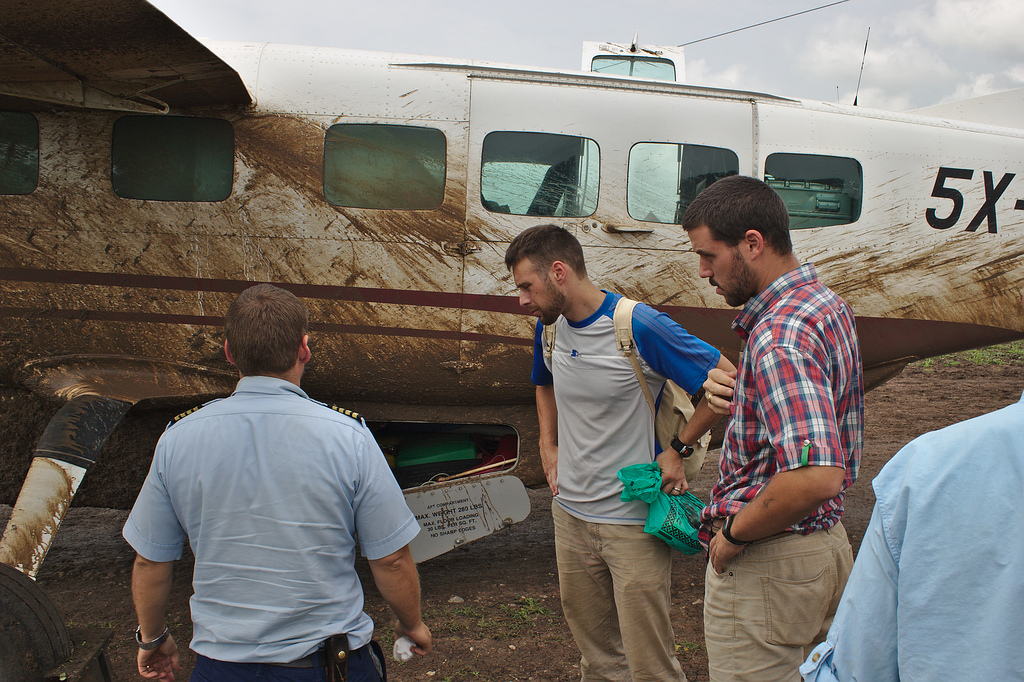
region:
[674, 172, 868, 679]
Young man wearing check shirt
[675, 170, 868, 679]
Man in check shirt wearing brown pants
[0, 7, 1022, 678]
Men standing close to the aircraft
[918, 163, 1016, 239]
5X on the aircraft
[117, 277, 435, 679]
Man in blue uniform has brown hair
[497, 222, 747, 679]
Man in gray and blue shirt has clean cut hair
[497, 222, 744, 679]
Man in gray and blue shirt wearing brown pants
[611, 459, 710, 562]
Blue plastic bag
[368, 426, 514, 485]
Luggages inside the compartment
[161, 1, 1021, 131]
cloud in daytime sky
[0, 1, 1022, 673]
plane above dirt surface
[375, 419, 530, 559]
open door of compartment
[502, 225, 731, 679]
man with straps on shoulders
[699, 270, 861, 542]
plaid shirt with short sleeves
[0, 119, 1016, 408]
mud on side of plane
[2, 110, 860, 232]
row of square windows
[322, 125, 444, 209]
surface of sirty window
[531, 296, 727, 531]
white shirt with blue sleeves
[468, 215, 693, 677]
man wearing white shirt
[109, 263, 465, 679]
man wearing blue shirt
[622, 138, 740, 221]
glass is clean and clear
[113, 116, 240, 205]
glass is clean and clear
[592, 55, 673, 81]
glass is clean and clear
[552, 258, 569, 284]
person has a white ear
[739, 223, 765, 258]
person has a white ear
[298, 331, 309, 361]
person has a white ear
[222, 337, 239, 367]
person has a white ear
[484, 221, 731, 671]
Man wearing blue and white shirt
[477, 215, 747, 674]
Man with dark hair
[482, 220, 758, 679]
Man with facial hair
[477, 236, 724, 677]
Man with a beard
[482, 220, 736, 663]
Man with khaki pants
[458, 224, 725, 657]
Man with beige backpack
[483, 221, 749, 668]
Man with black watch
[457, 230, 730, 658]
Man with green bandanna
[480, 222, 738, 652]
Man with arms akimbo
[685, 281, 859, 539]
The plaid shirt the man is wearing.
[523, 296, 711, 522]
The blue and gray shirt the man is wearing.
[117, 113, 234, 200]
glass window on plane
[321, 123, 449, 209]
glass window on plane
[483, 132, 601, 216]
glass window on plane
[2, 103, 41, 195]
window on side of small plane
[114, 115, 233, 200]
window on side of small plane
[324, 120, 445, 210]
window on side of small plane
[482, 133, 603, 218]
window on side of small plane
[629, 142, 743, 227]
window on side of small plane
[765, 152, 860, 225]
window on side of small plane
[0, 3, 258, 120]
wing on side of small plane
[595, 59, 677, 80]
window on side of small plane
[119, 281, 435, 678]
person standing next to plane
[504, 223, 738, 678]
person standing next to plane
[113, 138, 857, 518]
people next to plane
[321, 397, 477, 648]
arm of the man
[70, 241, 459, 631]
man in a blue outfit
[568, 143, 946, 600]
man in a patterned shirt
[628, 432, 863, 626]
arm of the man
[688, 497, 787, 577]
watch on the man's arm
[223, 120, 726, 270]
windows on the plane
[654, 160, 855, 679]
A person is standing up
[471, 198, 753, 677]
A person is standing up